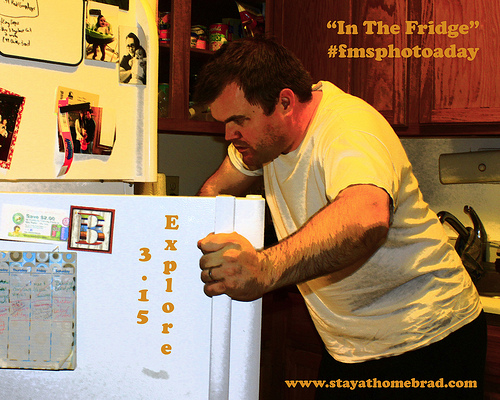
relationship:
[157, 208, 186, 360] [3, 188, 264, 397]
letters on door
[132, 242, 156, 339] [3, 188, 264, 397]
numbers on door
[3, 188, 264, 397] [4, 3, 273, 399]
door of refrigerator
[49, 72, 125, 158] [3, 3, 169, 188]
photos on door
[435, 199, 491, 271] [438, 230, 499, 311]
knives on counter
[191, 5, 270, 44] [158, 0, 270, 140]
food in cabinet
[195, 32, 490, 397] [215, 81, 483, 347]
man in t shirt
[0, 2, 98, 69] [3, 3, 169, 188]
board on door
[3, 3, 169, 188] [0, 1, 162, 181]
door of refrigerator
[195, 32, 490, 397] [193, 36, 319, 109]
man with hair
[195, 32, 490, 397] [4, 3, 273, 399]
man looking into refrigerator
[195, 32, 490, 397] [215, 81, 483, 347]
man wearing t shirt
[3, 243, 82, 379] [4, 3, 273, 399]
calendar on refrigerator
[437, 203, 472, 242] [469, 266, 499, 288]
faucet of sink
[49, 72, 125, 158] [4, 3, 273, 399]
photos on refrigerator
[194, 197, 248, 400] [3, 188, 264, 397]
handle of door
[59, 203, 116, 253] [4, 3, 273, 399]
magnet of refrigerator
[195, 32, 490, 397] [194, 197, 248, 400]
man holds handle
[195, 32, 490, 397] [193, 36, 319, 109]
man has hair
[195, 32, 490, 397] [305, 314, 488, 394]
man wearing pants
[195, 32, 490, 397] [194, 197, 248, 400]
man holding handle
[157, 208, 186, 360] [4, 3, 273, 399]
letters on refrigerator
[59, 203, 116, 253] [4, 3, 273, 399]
magnet on refrigerator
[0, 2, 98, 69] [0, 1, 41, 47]
board with writing